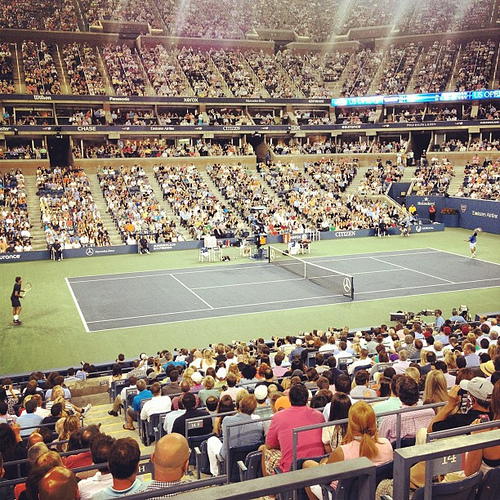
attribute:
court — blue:
[50, 230, 498, 325]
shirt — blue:
[223, 415, 266, 456]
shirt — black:
[10, 282, 30, 298]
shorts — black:
[7, 295, 23, 308]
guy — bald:
[132, 433, 199, 497]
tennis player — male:
[6, 271, 29, 333]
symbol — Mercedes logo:
[325, 264, 366, 317]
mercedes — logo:
[337, 270, 353, 300]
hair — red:
[339, 395, 384, 464]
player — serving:
[458, 223, 485, 265]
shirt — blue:
[465, 232, 486, 240]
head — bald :
[150, 432, 190, 477]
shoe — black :
[103, 406, 118, 420]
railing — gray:
[281, 409, 449, 439]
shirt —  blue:
[262, 407, 328, 474]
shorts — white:
[450, 235, 480, 280]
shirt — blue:
[445, 197, 484, 317]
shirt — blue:
[470, 230, 478, 242]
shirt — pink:
[266, 403, 325, 471]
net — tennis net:
[267, 246, 356, 301]